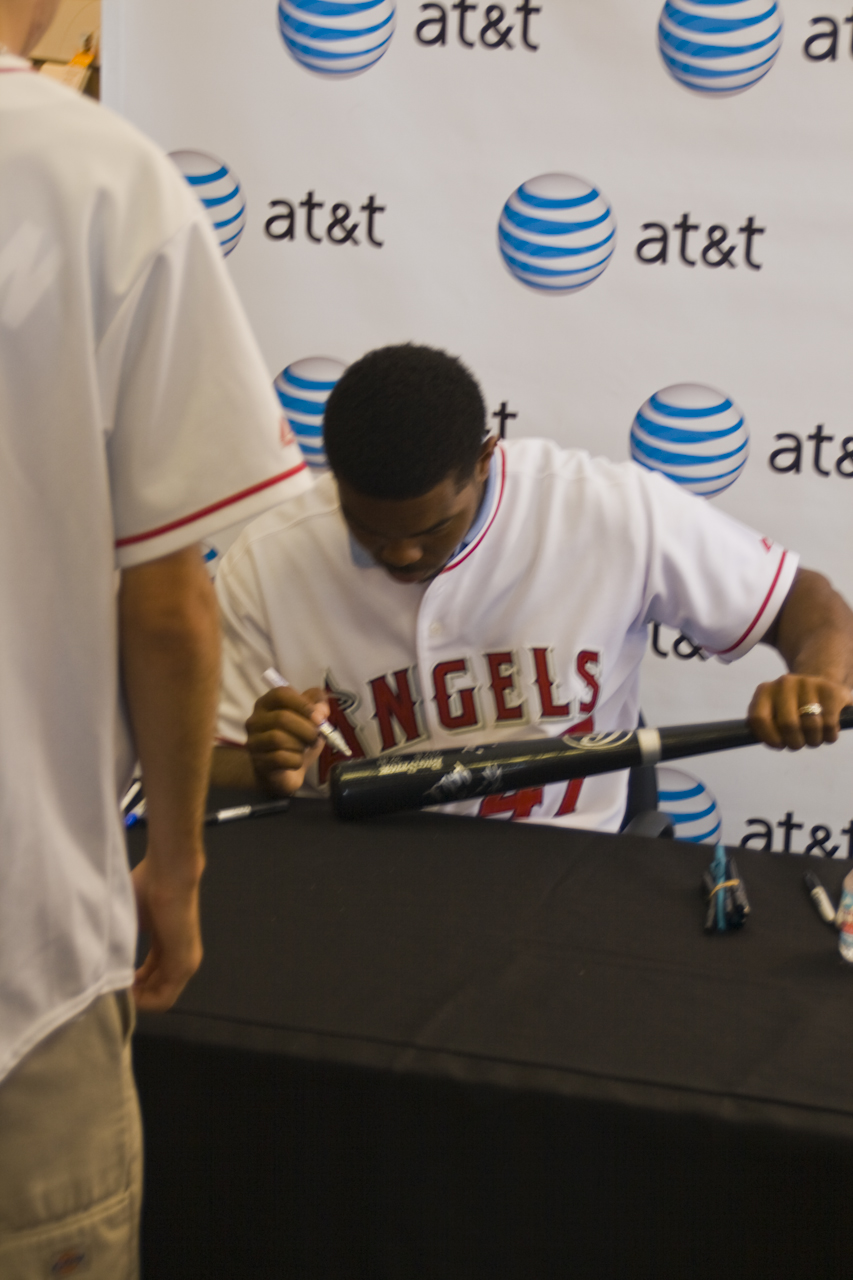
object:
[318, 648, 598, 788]
angels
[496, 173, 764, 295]
advertisement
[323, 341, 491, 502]
hair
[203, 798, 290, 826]
marker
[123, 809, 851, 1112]
cloth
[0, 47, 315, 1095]
shirt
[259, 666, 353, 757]
marker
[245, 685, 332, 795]
hand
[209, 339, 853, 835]
man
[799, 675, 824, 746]
finger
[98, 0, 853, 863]
wall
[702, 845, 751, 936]
pens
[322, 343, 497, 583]
head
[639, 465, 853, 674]
arm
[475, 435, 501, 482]
ear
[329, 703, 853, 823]
bat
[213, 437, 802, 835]
jersey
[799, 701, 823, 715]
ring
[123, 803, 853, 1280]
table